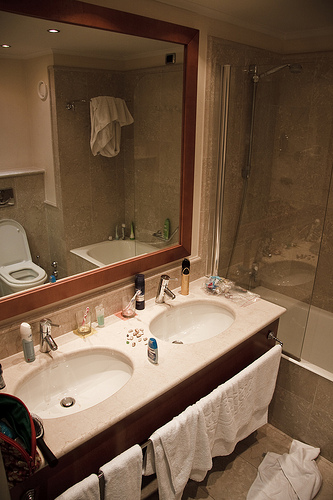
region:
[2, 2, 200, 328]
large bathroom mirror in brown frame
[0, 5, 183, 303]
mirror reflecting toilet and end of tub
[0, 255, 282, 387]
toiletries on edge of sinks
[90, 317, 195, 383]
pills and container between sinks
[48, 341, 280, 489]
used towels hanging on rods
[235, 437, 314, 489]
rumpled towel on tan floor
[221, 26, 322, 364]
glass panel leaning from tub to wall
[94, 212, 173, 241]
containers on sides of tub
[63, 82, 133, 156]
towel hanging from silver rod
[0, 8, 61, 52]
small white lights shining from ceiling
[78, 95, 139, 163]
reflection of towel in mirror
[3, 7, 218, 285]
mirror hung above sinks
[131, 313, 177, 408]
deodorant on the counter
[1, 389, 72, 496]
bag on the counter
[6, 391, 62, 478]
the bag is red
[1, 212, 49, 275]
toilet seat cover is up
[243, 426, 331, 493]
towel on the floor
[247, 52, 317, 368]
shower door made of glass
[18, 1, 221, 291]
mirror frame is brown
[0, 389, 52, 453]
the bag is open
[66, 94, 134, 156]
white towel hanging down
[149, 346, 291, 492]
white towel hanging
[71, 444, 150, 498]
two small white hand towels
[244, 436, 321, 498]
white towel on the floor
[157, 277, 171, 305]
metal sink faucet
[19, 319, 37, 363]
toiletry on sink counter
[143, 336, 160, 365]
deodorant on counter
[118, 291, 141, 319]
toothbrush in a glass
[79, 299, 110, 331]
glass filled with a toothbrush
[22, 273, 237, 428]
two sinks and counter in a bathroom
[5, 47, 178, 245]
Large bathroom mirror on wall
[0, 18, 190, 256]
Wooden frame on bathroom mirror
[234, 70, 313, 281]
Glass shower door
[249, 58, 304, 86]
Chrome fixed-position shower head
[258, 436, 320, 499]
towel on bathroom floor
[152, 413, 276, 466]
large towel on towel rack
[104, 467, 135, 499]
Small towel on towel rack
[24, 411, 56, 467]
Hairbrush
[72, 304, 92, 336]
Red and white toothbrush in glass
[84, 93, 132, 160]
reflection of the towel rack inside shower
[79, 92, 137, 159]
a towel hanging on a towelrack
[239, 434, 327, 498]
a white towel on the floor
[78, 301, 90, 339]
a toothbrush in the cup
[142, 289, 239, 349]
a white sink in a bathroom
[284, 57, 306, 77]
a shower head above the tub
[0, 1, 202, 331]
a large mirror on the wall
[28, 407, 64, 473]
a hair brush sitting on the bathroom counter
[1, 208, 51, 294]
a white toilet in the reflection of the mirror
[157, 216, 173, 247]
a green bottle of shampoo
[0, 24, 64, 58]
two lights in the ceiling